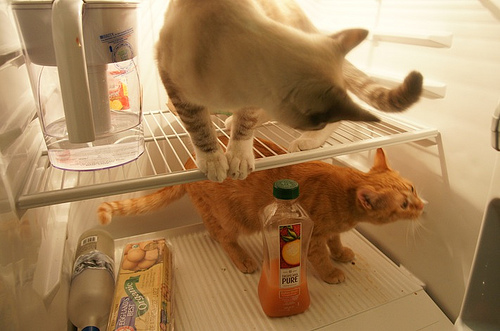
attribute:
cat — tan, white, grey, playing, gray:
[145, 0, 429, 181]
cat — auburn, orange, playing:
[97, 130, 433, 289]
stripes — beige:
[158, 59, 430, 155]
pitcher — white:
[6, 1, 161, 178]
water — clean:
[28, 107, 151, 174]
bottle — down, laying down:
[56, 222, 120, 329]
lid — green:
[269, 177, 304, 201]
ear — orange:
[351, 178, 380, 217]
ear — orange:
[368, 146, 392, 172]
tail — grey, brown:
[302, 7, 429, 126]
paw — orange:
[312, 261, 352, 289]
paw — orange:
[327, 242, 362, 269]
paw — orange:
[223, 252, 263, 279]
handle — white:
[45, 1, 115, 150]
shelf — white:
[114, 222, 452, 330]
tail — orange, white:
[94, 169, 189, 231]